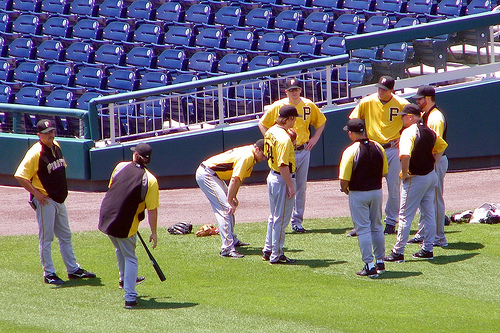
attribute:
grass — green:
[30, 230, 500, 310]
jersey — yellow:
[267, 127, 311, 177]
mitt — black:
[165, 212, 195, 247]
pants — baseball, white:
[200, 156, 253, 246]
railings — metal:
[115, 62, 363, 133]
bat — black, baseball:
[135, 231, 169, 299]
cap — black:
[287, 70, 304, 94]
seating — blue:
[56, 14, 318, 92]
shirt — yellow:
[264, 131, 298, 177]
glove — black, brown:
[168, 221, 207, 242]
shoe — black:
[44, 254, 87, 315]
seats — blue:
[56, 26, 229, 73]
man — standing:
[33, 116, 78, 291]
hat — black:
[278, 100, 310, 129]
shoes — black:
[50, 266, 93, 288]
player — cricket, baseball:
[230, 108, 314, 248]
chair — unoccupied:
[193, 20, 235, 70]